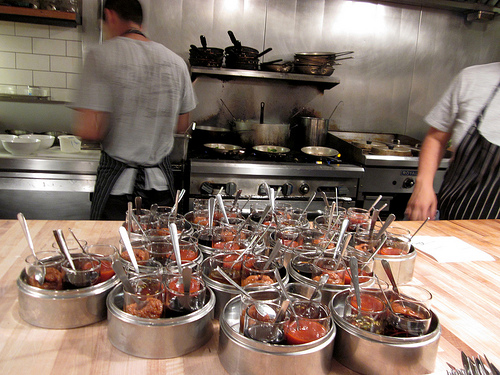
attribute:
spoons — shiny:
[11, 180, 433, 312]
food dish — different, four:
[122, 277, 163, 319]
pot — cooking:
[292, 108, 332, 145]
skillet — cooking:
[297, 138, 349, 169]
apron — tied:
[108, 152, 189, 221]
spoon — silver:
[17, 215, 46, 284]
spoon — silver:
[118, 222, 143, 286]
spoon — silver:
[167, 222, 192, 287]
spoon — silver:
[344, 252, 371, 324]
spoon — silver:
[379, 257, 405, 310]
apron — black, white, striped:
[87, 25, 179, 216]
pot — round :
[337, 282, 439, 372]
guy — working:
[70, 21, 208, 197]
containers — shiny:
[145, 331, 190, 351]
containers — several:
[17, 185, 457, 370]